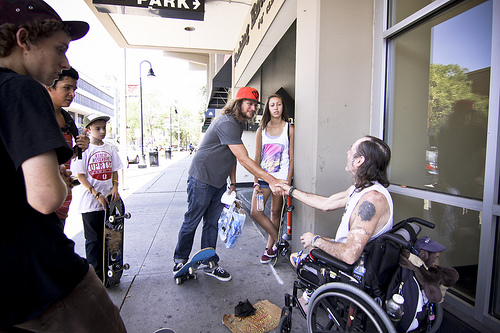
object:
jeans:
[174, 183, 226, 263]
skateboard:
[173, 247, 218, 286]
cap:
[236, 87, 265, 106]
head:
[233, 86, 264, 119]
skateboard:
[101, 196, 132, 287]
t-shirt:
[0, 66, 84, 318]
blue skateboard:
[172, 247, 217, 285]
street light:
[138, 59, 153, 166]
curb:
[121, 151, 186, 198]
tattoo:
[358, 200, 375, 222]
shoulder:
[356, 191, 389, 217]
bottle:
[256, 191, 265, 212]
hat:
[1, 0, 90, 41]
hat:
[83, 112, 110, 129]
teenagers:
[0, 0, 114, 333]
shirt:
[187, 115, 242, 186]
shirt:
[69, 141, 124, 215]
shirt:
[332, 183, 393, 244]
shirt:
[254, 122, 293, 186]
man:
[172, 87, 289, 280]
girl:
[249, 93, 296, 265]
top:
[257, 124, 288, 182]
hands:
[268, 178, 288, 196]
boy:
[172, 87, 283, 288]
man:
[272, 137, 406, 316]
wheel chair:
[293, 217, 438, 322]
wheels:
[209, 260, 215, 268]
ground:
[52, 132, 322, 331]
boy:
[74, 111, 126, 283]